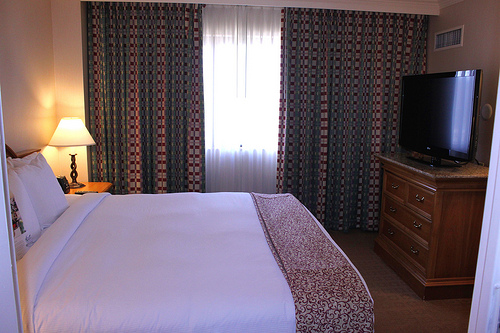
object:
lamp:
[44, 114, 99, 189]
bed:
[0, 132, 398, 330]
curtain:
[315, 30, 364, 104]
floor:
[364, 280, 415, 307]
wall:
[16, 20, 64, 63]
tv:
[397, 71, 487, 162]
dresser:
[385, 162, 432, 270]